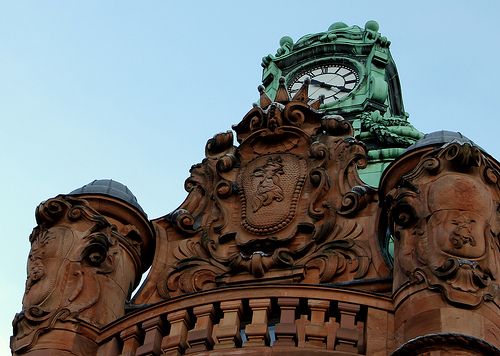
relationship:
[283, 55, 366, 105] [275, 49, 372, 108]
clock has numerals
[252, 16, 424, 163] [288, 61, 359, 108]
clock has hands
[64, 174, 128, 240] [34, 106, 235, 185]
top of a red column on a balcony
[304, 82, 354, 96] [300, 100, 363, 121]
minute hand at twenty on a clock face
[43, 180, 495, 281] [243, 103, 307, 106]
fancy brown architecture with clock